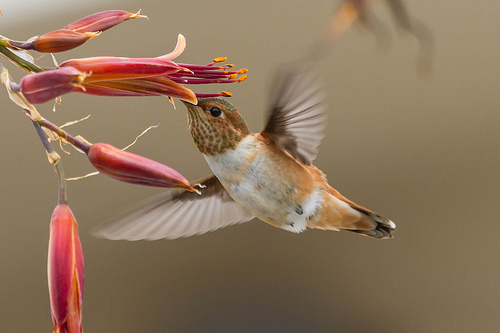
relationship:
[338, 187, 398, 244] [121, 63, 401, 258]
feathers of bird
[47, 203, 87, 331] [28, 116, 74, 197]
flower on stem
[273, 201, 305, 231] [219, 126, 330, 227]
feet close to body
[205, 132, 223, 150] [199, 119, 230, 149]
spots on chin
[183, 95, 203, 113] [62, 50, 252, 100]
beak inside flower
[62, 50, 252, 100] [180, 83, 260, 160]
flower over head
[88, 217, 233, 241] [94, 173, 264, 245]
tips of wing